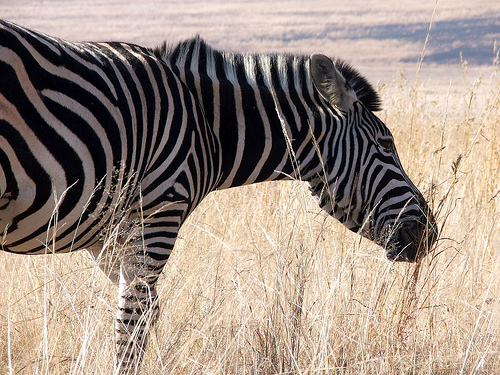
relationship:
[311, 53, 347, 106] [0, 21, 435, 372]
ear of a zebra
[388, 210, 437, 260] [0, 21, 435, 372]
snout of a zebra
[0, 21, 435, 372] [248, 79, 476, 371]
zebra in grass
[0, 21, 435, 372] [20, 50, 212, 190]
zebra has a pattern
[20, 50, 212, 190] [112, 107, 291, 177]
pattern on its fur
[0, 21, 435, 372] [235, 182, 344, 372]
zebra in grass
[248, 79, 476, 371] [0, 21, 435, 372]
grass surrounds zebra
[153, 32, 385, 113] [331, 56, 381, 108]
mane of hair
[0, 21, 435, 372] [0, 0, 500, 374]
zebra not eating grass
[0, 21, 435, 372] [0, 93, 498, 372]
zebra stands in field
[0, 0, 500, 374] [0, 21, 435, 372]
grass around zebra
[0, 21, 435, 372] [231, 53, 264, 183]
zebra has stripe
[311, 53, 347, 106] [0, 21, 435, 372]
ear of zebra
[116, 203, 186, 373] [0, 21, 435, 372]
leg of zebra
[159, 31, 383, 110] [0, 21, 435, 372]
mane on zebra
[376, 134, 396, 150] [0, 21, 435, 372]
eye on zebra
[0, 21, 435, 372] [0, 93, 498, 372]
zebra standing in field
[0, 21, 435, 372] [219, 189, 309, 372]
zebra eating tall grass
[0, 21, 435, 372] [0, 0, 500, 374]
zebra eating grass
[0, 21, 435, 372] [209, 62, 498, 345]
zebra eating grass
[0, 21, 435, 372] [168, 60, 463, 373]
zebra eating grass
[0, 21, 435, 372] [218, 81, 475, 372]
zebra eating grass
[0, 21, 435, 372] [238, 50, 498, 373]
zebra eating grass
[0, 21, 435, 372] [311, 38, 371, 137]
zebra has an ear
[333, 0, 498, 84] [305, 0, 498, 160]
shadow on land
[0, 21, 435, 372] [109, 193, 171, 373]
zebra has a leg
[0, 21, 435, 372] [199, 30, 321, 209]
zebra has a neck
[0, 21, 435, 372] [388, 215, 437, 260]
zebra has a snout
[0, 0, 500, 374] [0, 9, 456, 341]
grass near zebra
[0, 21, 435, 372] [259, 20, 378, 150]
zebra has ears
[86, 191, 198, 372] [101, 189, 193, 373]
stripes on legs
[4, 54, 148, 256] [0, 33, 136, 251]
stripes on flank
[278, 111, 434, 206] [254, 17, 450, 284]
stripes on face